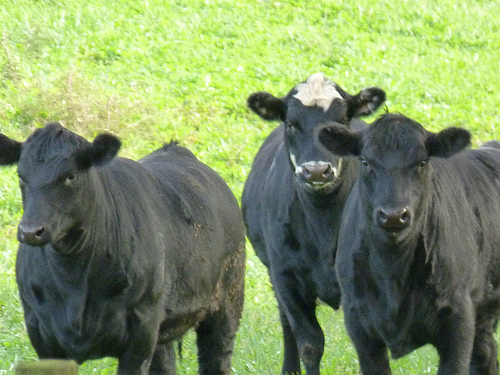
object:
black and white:
[289, 73, 350, 139]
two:
[0, 75, 383, 375]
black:
[116, 165, 221, 286]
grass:
[69, 11, 227, 70]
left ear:
[1, 129, 25, 168]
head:
[0, 119, 123, 247]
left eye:
[15, 172, 27, 185]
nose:
[17, 222, 46, 242]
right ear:
[83, 131, 123, 165]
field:
[0, 0, 495, 375]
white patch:
[291, 75, 340, 107]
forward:
[207, 132, 255, 167]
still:
[0, 75, 500, 375]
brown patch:
[42, 84, 108, 129]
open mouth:
[302, 177, 333, 188]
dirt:
[217, 241, 257, 329]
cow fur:
[218, 266, 243, 313]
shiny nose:
[16, 224, 47, 246]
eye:
[285, 122, 297, 130]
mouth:
[377, 226, 410, 236]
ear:
[426, 127, 474, 158]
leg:
[437, 280, 472, 375]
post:
[14, 354, 85, 375]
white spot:
[297, 79, 344, 106]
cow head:
[251, 71, 392, 195]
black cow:
[236, 76, 381, 375]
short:
[418, 11, 469, 50]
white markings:
[289, 151, 302, 173]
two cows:
[235, 75, 500, 375]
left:
[0, 0, 262, 373]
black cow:
[321, 112, 500, 375]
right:
[240, 0, 500, 375]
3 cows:
[0, 121, 247, 375]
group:
[0, 68, 500, 375]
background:
[0, 0, 500, 167]